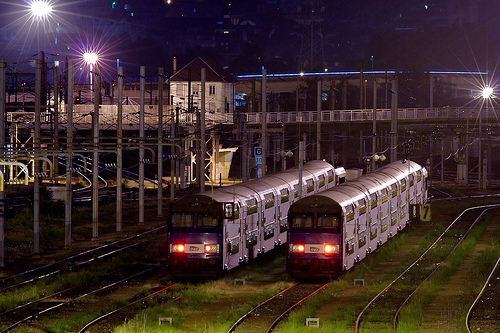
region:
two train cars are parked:
[170, 160, 427, 278]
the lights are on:
[297, 245, 333, 255]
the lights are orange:
[177, 245, 210, 252]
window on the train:
[227, 238, 239, 252]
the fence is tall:
[0, 52, 251, 270]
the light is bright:
[481, 85, 491, 99]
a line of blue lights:
[237, 68, 394, 78]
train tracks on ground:
[0, 191, 497, 330]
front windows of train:
[171, 213, 218, 225]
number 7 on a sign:
[418, 203, 429, 220]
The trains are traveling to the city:
[20, 31, 481, 311]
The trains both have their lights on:
[55, 25, 445, 310]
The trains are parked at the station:
[62, 53, 488, 313]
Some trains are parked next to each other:
[55, 36, 470, 306]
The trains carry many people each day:
[76, 55, 476, 315]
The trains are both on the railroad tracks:
[27, 46, 472, 308]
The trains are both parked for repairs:
[54, 43, 469, 303]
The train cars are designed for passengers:
[25, 45, 465, 300]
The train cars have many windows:
[41, 65, 476, 311]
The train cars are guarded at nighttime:
[52, 23, 462, 299]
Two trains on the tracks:
[161, 153, 432, 283]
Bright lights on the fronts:
[163, 236, 343, 264]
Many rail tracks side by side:
[0, 188, 498, 331]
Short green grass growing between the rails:
[0, 198, 498, 331]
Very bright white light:
[475, 79, 499, 107]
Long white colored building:
[0, 50, 499, 186]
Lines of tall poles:
[0, 49, 498, 270]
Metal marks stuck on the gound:
[152, 271, 367, 331]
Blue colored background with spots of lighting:
[0, 0, 498, 85]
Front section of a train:
[286, 193, 345, 283]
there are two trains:
[127, 135, 467, 298]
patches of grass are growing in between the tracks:
[104, 263, 291, 330]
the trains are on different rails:
[125, 133, 450, 290]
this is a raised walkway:
[230, 87, 495, 136]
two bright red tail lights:
[287, 230, 338, 258]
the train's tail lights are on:
[152, 237, 239, 255]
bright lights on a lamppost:
[65, 25, 114, 79]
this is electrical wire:
[20, 38, 212, 189]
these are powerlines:
[17, 36, 200, 151]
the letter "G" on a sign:
[248, 143, 265, 158]